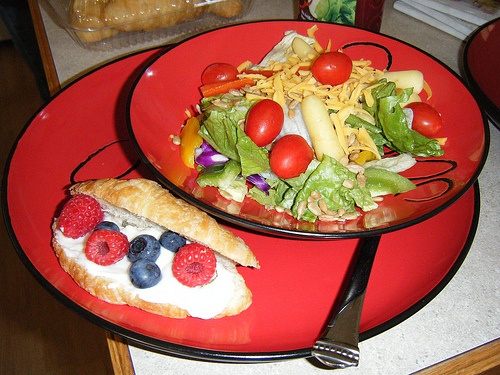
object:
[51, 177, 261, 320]
treat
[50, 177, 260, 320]
bread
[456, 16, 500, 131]
fruit dish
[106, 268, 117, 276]
cream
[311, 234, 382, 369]
metal utensil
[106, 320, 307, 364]
black trim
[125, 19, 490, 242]
bowl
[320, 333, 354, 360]
part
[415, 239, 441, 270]
part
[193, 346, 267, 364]
edge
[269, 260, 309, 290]
part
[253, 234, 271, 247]
part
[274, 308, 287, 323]
part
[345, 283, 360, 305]
part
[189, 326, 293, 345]
utensil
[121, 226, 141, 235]
cream cheese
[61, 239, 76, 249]
cream cheese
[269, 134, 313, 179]
cherry tomato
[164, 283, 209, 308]
cream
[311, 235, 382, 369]
fork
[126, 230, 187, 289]
blueberry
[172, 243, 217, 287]
raspberry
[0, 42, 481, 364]
plate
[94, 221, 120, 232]
cherry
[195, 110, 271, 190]
lettuce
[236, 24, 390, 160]
cheese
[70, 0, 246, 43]
container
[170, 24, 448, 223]
vegetable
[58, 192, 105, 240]
cranberry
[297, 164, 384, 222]
seeds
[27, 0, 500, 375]
counter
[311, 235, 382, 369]
handle